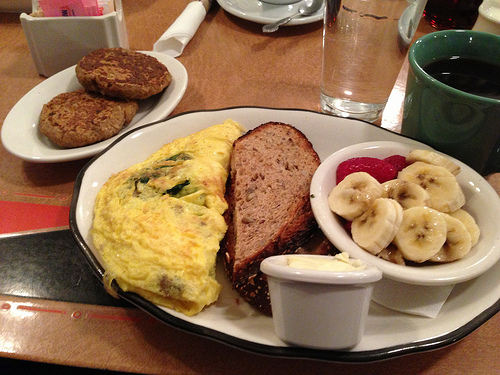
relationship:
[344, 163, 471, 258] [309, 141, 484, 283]
bananas in bowl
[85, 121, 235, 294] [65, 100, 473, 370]
omelet on plate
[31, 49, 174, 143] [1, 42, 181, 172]
sausage on plate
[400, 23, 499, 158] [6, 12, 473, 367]
cup on table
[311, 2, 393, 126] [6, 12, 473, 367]
glass on table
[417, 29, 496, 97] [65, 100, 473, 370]
rim on plate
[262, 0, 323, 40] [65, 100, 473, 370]
spoon on plate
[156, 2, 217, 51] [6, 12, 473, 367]
napkin on table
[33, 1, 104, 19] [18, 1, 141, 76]
packets on container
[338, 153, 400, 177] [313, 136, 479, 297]
strawberries in bowl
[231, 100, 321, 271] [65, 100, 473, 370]
toast on plate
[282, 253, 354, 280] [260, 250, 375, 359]
butter in cup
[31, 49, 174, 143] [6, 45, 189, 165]
sausage on plate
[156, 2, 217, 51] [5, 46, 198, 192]
napkin on plate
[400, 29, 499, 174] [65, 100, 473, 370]
cup by plate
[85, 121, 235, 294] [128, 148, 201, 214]
omelet with filling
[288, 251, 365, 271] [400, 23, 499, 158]
butter in cup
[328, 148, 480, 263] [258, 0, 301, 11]
bananas in bowl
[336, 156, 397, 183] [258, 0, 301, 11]
strawberries in bowl